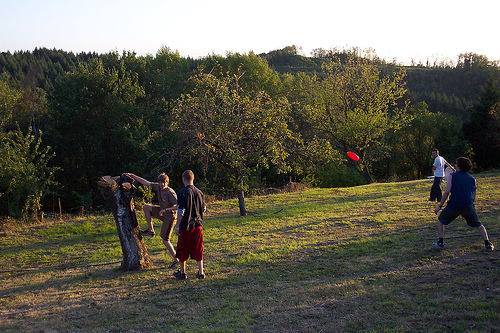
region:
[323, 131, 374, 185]
Red Frisbee soaring aloft.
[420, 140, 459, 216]
Arm extension threw Frisbee.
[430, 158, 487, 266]
Wrong position catch Frisbee.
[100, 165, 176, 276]
Trying climb old tree stump.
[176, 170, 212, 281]
Red shorts riding low.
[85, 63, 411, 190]
Trees hedges border field.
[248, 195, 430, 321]
Field contains dry grass.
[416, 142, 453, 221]
Only boy long pants.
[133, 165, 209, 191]
Both boys red hair.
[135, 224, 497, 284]
Three boys sneaker feet.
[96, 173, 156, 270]
a tree stump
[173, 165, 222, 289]
a man in a field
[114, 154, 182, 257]
a boy about to get on stump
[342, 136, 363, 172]
a red frisbee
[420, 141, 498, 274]
two people playing frisbee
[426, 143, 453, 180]
a man in a white shirt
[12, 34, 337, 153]
hill full of trees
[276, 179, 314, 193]
a dirt pile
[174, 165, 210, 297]
a boy wearing red shorts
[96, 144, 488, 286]
four men on a field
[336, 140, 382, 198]
A flying freesbee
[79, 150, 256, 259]
Two guys looking at each other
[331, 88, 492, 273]
Two men playing Frisbee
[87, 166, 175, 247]
A guy with his foot on a tree bark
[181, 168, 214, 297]
A guy with a red pants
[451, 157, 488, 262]
A guy with blue shirt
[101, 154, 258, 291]
Two guys standing on a field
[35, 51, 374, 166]
Green trees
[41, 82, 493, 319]
Four men on a field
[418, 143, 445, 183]
A man with a white shirt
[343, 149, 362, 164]
a red Frisbee in the air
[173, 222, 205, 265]
a pair of red shorts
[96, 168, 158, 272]
a brown tree stump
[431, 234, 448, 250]
a black and white shoe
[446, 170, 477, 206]
a blue shirt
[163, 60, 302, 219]
a small green tree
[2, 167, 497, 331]
a green and brown grassy field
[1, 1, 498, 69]
a pale blue and gray sky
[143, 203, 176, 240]
a tan pair of shorts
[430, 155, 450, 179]
a white shirt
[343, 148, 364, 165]
The red Frisbee in the air.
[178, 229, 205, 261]
The red long shorts worn by the boy.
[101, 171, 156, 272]
The tree stump the boy has his foot on.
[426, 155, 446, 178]
The white t-shirt worn by the guy in black pants.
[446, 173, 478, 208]
The dark blue tank top worn by the boy in black shorts.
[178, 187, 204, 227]
The brown shirt worn by the guy in red shorts.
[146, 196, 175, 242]
The brown and black shorts worn by the boy with his foot on the tree stump.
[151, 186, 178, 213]
The brown t-shirt the boy is wearing.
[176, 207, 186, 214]
The white undershirt pushed up the boy in red shorts has on.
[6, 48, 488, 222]
The trees in the background.